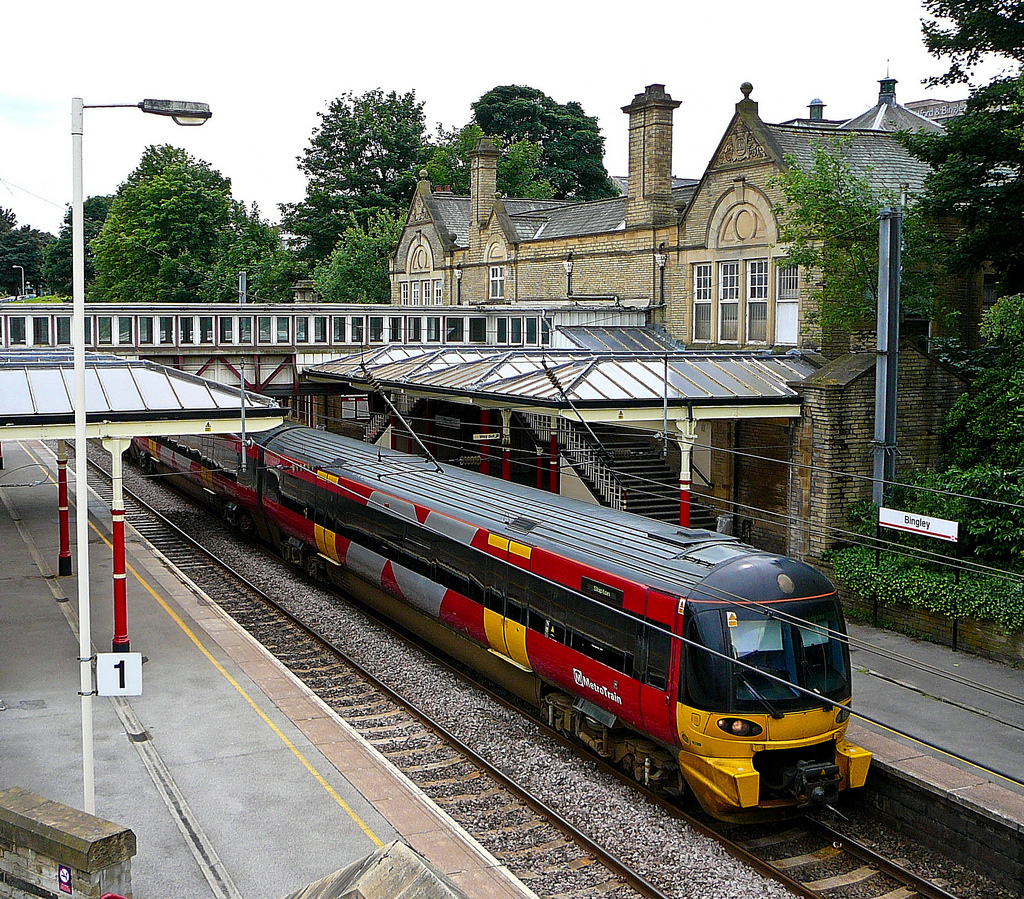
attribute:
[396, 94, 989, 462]
building — large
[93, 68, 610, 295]
trees — row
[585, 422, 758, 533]
cases — two stair, set 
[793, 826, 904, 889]
tracks — above , train 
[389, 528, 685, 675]
windows — row 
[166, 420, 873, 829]
train — front end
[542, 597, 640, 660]
window — passenger 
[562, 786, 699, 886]
gravel — gray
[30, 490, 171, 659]
poles — red, for trains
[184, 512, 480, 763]
tracks — metal, for trains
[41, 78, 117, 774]
street light — white, tall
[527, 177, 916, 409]
building — brick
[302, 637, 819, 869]
tracks — train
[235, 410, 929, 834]
train — yellow, red